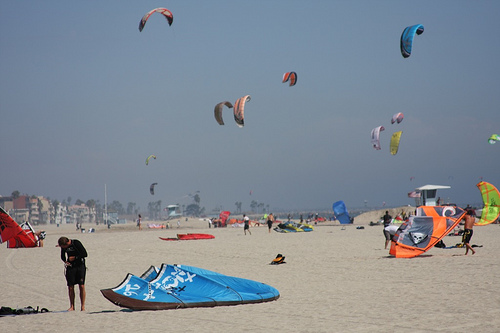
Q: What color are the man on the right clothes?
A: Black.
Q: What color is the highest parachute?
A: Red.